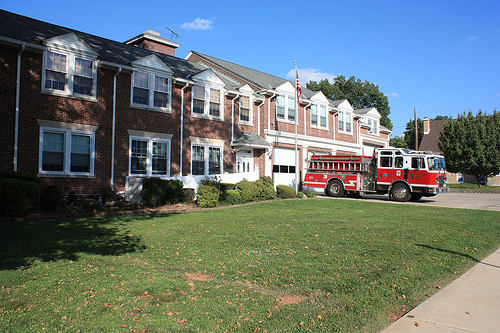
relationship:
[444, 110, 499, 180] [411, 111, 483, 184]
leaves are growing from trees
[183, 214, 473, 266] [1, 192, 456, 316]
grass wiring in front lawn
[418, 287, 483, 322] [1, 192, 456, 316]
sidewalk surrounds front lawn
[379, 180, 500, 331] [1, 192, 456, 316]
sidewalk surrounds front lawn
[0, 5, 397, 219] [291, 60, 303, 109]
fire station hurls a flag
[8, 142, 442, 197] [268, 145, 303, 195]
bottom floor holds garage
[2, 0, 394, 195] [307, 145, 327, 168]
fire house holds garage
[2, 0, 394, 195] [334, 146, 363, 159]
fire house holds garage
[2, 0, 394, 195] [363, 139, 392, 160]
fire house holds garage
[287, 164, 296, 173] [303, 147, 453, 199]
window guides firetruck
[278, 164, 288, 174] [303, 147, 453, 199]
window guides firetruck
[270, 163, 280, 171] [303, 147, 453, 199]
window guides firetruck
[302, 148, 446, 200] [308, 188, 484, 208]
fire truck sits on drive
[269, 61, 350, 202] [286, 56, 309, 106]
pole supports flag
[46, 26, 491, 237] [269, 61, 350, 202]
building supports pole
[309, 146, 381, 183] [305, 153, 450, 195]
ladder attached to fire truck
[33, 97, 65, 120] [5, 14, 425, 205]
brick covering building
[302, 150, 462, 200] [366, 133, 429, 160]
fire truck in front of floor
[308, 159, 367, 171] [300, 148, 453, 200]
ladder secured to fire truck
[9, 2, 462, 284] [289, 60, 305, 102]
fire department sports a flag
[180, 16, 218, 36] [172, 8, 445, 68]
cloud floats through sky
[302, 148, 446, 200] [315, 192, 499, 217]
fire truck parked in driveway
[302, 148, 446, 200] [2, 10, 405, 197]
fire truck reflects good will for firehouse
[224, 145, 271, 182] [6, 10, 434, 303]
doors are closed at front of fire department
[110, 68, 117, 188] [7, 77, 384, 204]
downpipe secured to building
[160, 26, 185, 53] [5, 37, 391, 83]
antenna secured to roof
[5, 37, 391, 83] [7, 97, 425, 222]
roof covering building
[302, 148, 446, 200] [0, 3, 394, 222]
fire truck in front of fire station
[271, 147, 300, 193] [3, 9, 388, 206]
door on fire station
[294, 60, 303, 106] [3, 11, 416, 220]
american flag in front of building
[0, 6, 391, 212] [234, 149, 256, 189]
building has door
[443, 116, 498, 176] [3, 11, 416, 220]
tree in front of building